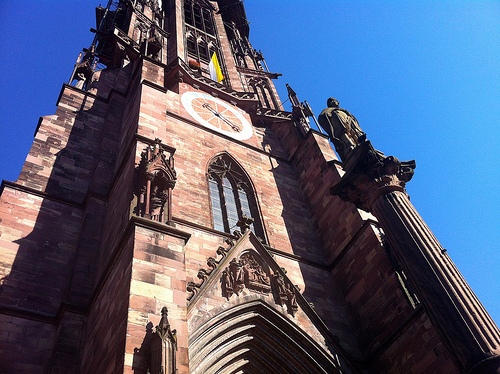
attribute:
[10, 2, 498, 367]
tower — brick, tall, block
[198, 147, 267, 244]
window — arched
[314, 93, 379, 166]
statue — person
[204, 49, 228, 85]
flag — yellow, white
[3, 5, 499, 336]
sky — blue, clear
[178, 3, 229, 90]
window — large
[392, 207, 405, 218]
ridges — recess